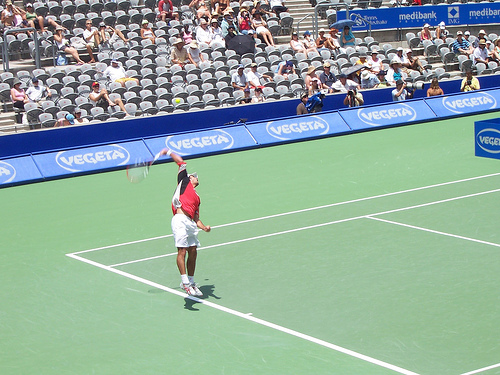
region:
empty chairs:
[143, 67, 219, 102]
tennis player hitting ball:
[128, 142, 224, 310]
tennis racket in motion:
[121, 152, 170, 187]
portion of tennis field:
[227, 167, 489, 355]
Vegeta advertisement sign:
[257, 115, 352, 145]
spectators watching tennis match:
[231, 61, 273, 88]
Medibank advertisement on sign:
[398, 9, 445, 31]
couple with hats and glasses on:
[6, 72, 67, 113]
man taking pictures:
[391, 75, 414, 105]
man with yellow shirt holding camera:
[461, 62, 488, 99]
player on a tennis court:
[113, 144, 273, 279]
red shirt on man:
[161, 186, 233, 226]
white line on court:
[400, 207, 457, 259]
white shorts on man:
[154, 221, 215, 261]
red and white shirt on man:
[161, 188, 219, 309]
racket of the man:
[115, 155, 165, 190]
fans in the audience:
[171, 22, 326, 104]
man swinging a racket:
[86, 120, 303, 307]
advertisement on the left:
[249, 108, 336, 169]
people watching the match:
[77, 13, 142, 46]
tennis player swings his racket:
[124, 139, 217, 305]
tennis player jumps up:
[123, 139, 223, 306]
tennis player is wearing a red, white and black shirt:
[128, 130, 223, 311]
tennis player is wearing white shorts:
[125, 136, 215, 306]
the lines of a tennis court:
[66, 166, 497, 371]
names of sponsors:
[341, 3, 498, 33]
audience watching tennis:
[0, 1, 498, 137]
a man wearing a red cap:
[86, 77, 123, 112]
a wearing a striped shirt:
[453, 27, 467, 52]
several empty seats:
[13, 5, 383, 124]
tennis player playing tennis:
[104, 120, 255, 315]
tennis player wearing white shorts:
[148, 136, 213, 256]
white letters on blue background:
[179, 129, 292, 151]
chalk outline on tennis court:
[222, 201, 350, 374]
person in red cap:
[77, 70, 129, 113]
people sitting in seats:
[9, 74, 71, 109]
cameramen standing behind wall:
[282, 77, 398, 124]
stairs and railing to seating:
[259, 4, 354, 41]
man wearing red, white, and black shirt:
[139, 144, 224, 249]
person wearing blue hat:
[41, 109, 107, 134]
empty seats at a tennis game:
[134, 65, 195, 103]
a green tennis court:
[0, 115, 497, 371]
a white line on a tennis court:
[116, 265, 401, 368]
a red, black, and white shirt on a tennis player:
[169, 164, 207, 222]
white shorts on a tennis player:
[169, 211, 205, 249]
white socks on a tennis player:
[176, 273, 190, 284]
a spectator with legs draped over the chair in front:
[86, 78, 132, 115]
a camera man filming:
[342, 85, 367, 110]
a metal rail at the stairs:
[298, 1, 369, 39]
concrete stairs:
[283, 2, 339, 37]